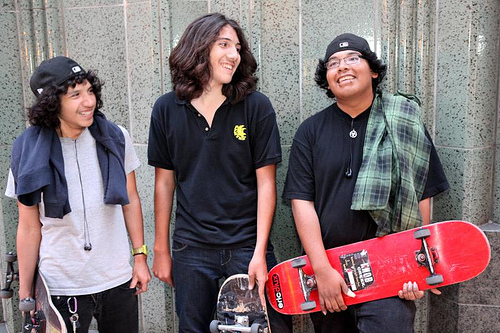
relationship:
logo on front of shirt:
[233, 122, 248, 142] [147, 86, 282, 250]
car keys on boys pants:
[67, 297, 83, 331] [50, 280, 140, 331]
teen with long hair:
[149, 12, 293, 331] [169, 12, 258, 104]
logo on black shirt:
[233, 122, 248, 142] [147, 86, 282, 250]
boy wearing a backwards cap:
[282, 32, 451, 331] [323, 34, 371, 59]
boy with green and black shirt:
[282, 32, 451, 331] [352, 90, 430, 235]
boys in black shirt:
[148, 13, 449, 331] [147, 86, 282, 250]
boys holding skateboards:
[4, 14, 450, 331] [24, 221, 491, 331]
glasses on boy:
[323, 53, 362, 69] [282, 32, 451, 331]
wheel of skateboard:
[415, 229, 430, 241] [267, 218, 491, 315]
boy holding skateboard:
[282, 32, 451, 331] [267, 218, 491, 315]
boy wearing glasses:
[282, 32, 451, 331] [323, 53, 362, 69]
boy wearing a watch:
[4, 57, 149, 332] [134, 244, 148, 253]